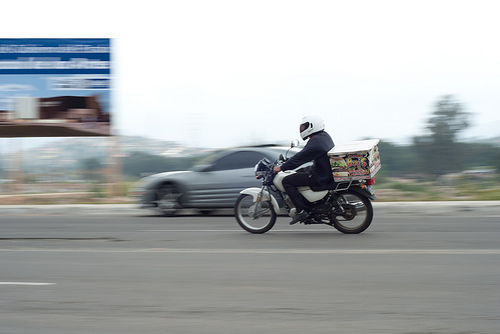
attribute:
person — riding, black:
[270, 114, 334, 222]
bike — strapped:
[235, 142, 383, 235]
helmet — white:
[299, 112, 326, 140]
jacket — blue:
[280, 132, 336, 192]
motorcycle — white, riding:
[235, 141, 382, 237]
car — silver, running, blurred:
[129, 142, 304, 219]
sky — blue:
[2, 1, 500, 148]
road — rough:
[1, 203, 499, 333]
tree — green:
[411, 93, 472, 177]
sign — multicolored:
[0, 38, 113, 138]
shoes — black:
[291, 205, 311, 224]